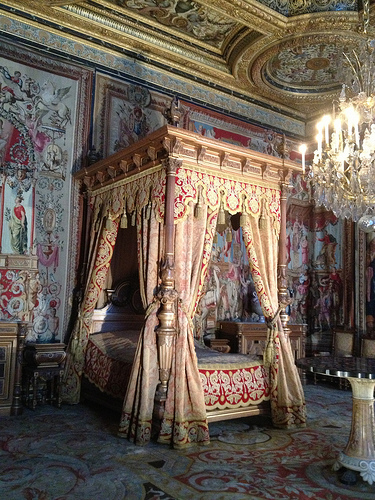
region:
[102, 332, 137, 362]
a bed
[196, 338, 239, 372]
comforter on the bed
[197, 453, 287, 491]
the floor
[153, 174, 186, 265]
a pole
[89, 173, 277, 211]
a canopy bed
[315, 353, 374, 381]
a table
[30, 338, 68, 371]
a brown side table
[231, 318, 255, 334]
a brown desk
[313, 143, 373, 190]
a chandelier with lights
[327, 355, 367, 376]
glass on the table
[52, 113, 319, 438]
An ornate bed set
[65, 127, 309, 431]
An artful bed canopy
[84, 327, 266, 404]
A red and white bed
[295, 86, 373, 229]
A fancy chandelier above the bed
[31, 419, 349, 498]
A well designed carpet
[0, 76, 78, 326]
Beautiful patterns on the wall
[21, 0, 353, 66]
Gold trim on the ceiling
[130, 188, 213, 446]
Multicolored bed curtains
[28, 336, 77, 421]
A bedside table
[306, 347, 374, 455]
A marble table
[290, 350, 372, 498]
dark marble round table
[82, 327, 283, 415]
a wueen size bed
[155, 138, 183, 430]
bed posts to the canopy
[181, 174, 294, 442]
draps hang from the canopy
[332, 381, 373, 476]
a column for the table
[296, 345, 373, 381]
a black table top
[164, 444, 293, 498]
print on the carpet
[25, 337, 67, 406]
the stand by the bed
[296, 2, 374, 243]
chandelier hangs from the ceiling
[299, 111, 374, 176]
the lights are on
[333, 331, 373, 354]
the back cushions of the chairs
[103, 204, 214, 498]
a bed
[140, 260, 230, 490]
a bed